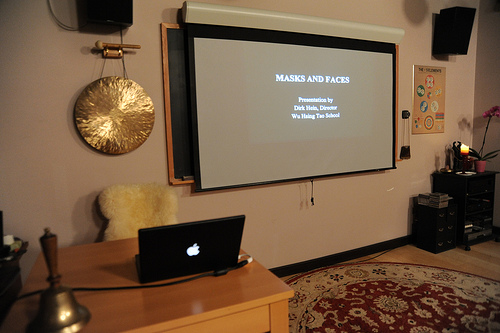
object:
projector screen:
[192, 36, 395, 194]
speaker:
[76, 0, 134, 35]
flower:
[480, 111, 490, 120]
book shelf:
[466, 214, 489, 222]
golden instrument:
[72, 75, 155, 156]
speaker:
[431, 6, 477, 55]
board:
[410, 64, 448, 135]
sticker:
[421, 74, 439, 88]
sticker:
[415, 85, 427, 100]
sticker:
[416, 99, 428, 114]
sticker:
[422, 112, 435, 130]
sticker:
[432, 86, 442, 96]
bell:
[18, 226, 95, 332]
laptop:
[133, 213, 247, 284]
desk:
[0, 232, 303, 332]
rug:
[283, 261, 500, 333]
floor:
[280, 239, 500, 282]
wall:
[0, 0, 481, 270]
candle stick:
[23, 225, 93, 332]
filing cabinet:
[413, 198, 465, 255]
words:
[274, 73, 308, 82]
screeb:
[186, 34, 396, 194]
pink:
[467, 106, 500, 161]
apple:
[186, 242, 201, 258]